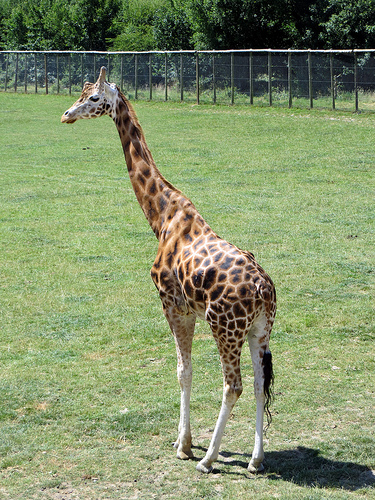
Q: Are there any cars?
A: No, there are no cars.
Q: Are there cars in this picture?
A: No, there are no cars.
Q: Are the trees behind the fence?
A: Yes, the trees are behind the fence.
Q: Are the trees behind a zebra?
A: No, the trees are behind the fence.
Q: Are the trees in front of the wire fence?
A: No, the trees are behind the fence.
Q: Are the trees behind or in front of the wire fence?
A: The trees are behind the fence.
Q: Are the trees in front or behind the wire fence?
A: The trees are behind the fence.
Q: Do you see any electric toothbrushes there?
A: No, there are no electric toothbrushes.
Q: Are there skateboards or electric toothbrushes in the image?
A: No, there are no electric toothbrushes or skateboards.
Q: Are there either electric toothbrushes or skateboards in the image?
A: No, there are no electric toothbrushes or skateboards.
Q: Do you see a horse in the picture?
A: No, there are no horses.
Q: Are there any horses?
A: No, there are no horses.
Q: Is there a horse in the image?
A: No, there are no horses.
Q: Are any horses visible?
A: No, there are no horses.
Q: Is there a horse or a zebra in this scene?
A: No, there are no horses or zebras.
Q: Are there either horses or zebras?
A: No, there are no horses or zebras.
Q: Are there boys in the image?
A: No, there are no boys.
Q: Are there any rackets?
A: No, there are no rackets.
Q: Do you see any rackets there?
A: No, there are no rackets.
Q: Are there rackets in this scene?
A: No, there are no rackets.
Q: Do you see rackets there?
A: No, there are no rackets.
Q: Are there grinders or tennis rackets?
A: No, there are no tennis rackets or grinders.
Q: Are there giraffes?
A: Yes, there is a giraffe.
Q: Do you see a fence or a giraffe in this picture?
A: Yes, there is a giraffe.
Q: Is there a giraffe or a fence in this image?
A: Yes, there is a giraffe.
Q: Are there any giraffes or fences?
A: Yes, there is a giraffe.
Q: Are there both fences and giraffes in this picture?
A: Yes, there are both a giraffe and a fence.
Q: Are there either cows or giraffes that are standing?
A: Yes, the giraffe is standing.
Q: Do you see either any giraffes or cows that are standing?
A: Yes, the giraffe is standing.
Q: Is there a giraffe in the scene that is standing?
A: Yes, there is a giraffe that is standing.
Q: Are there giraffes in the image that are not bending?
A: Yes, there is a giraffe that is standing.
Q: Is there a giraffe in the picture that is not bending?
A: Yes, there is a giraffe that is standing.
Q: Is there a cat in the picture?
A: No, there are no cats.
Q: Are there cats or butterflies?
A: No, there are no cats or butterflies.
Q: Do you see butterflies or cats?
A: No, there are no cats or butterflies.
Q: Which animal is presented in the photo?
A: The animal is a giraffe.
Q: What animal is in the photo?
A: The animal is a giraffe.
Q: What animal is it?
A: The animal is a giraffe.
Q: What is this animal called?
A: This is a giraffe.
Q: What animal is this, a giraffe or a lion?
A: This is a giraffe.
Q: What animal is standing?
A: The animal is a giraffe.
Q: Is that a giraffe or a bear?
A: That is a giraffe.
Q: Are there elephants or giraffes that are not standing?
A: No, there is a giraffe but it is standing.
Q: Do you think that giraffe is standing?
A: Yes, the giraffe is standing.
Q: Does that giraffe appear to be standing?
A: Yes, the giraffe is standing.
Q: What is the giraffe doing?
A: The giraffe is standing.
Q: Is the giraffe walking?
A: No, the giraffe is standing.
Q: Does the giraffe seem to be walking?
A: No, the giraffe is standing.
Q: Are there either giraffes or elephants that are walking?
A: No, there is a giraffe but it is standing.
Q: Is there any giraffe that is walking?
A: No, there is a giraffe but it is standing.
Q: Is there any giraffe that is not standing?
A: No, there is a giraffe but it is standing.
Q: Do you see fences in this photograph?
A: Yes, there is a fence.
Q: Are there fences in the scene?
A: Yes, there is a fence.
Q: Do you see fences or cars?
A: Yes, there is a fence.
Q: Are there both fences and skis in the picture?
A: No, there is a fence but no skis.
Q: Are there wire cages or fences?
A: Yes, there is a wire fence.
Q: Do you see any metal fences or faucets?
A: Yes, there is a metal fence.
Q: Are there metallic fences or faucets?
A: Yes, there is a metal fence.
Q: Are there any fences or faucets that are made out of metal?
A: Yes, the fence is made of metal.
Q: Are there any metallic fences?
A: Yes, there is a metal fence.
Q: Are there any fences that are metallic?
A: Yes, there is a fence that is metallic.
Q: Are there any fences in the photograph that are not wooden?
A: Yes, there is a metallic fence.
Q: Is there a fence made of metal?
A: Yes, there is a fence that is made of metal.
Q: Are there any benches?
A: No, there are no benches.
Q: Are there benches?
A: No, there are no benches.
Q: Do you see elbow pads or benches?
A: No, there are no benches or elbow pads.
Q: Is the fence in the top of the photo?
A: Yes, the fence is in the top of the image.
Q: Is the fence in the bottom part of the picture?
A: No, the fence is in the top of the image.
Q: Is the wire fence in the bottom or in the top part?
A: The fence is in the top of the image.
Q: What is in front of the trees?
A: The fence is in front of the trees.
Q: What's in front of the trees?
A: The fence is in front of the trees.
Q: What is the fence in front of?
A: The fence is in front of the trees.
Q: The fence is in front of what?
A: The fence is in front of the trees.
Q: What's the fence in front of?
A: The fence is in front of the trees.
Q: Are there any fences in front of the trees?
A: Yes, there is a fence in front of the trees.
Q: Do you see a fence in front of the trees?
A: Yes, there is a fence in front of the trees.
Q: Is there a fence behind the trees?
A: No, the fence is in front of the trees.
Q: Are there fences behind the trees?
A: No, the fence is in front of the trees.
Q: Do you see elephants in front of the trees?
A: No, there is a fence in front of the trees.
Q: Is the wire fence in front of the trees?
A: Yes, the fence is in front of the trees.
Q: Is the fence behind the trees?
A: No, the fence is in front of the trees.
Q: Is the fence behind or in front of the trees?
A: The fence is in front of the trees.